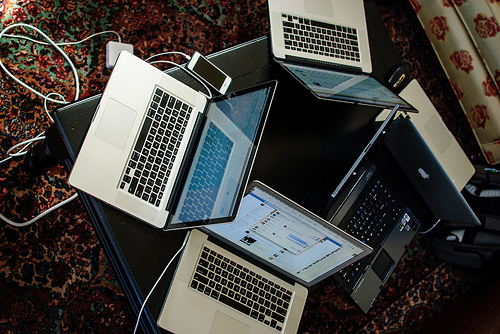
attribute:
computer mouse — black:
[386, 64, 409, 90]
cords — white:
[1, 17, 100, 268]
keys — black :
[130, 85, 192, 211]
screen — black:
[181, 97, 251, 206]